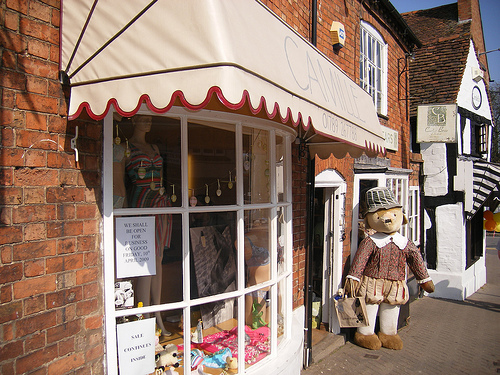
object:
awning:
[57, 0, 389, 159]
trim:
[66, 84, 389, 160]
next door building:
[408, 37, 499, 304]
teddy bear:
[331, 181, 437, 352]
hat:
[359, 182, 404, 218]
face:
[364, 206, 405, 236]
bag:
[331, 275, 371, 330]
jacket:
[341, 228, 432, 283]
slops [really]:
[347, 271, 413, 308]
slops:
[355, 273, 412, 309]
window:
[101, 98, 300, 373]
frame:
[102, 99, 290, 373]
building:
[398, 1, 497, 304]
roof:
[403, 33, 497, 125]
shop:
[404, 27, 500, 305]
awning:
[458, 157, 499, 221]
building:
[1, 0, 429, 374]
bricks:
[73, 232, 102, 253]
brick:
[44, 187, 87, 205]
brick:
[14, 310, 59, 339]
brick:
[23, 328, 47, 353]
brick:
[44, 315, 84, 349]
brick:
[53, 336, 75, 357]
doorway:
[310, 179, 342, 342]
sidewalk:
[300, 254, 499, 375]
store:
[58, 0, 390, 374]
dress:
[122, 136, 175, 254]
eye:
[392, 210, 399, 218]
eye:
[376, 215, 381, 221]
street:
[294, 228, 500, 373]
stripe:
[472, 163, 499, 176]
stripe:
[473, 171, 499, 187]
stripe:
[473, 168, 499, 183]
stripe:
[472, 200, 485, 208]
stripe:
[473, 180, 493, 196]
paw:
[418, 278, 436, 297]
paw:
[339, 277, 361, 298]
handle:
[340, 273, 357, 300]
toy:
[336, 287, 348, 300]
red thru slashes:
[348, 273, 414, 309]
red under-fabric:
[364, 277, 407, 306]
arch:
[313, 168, 346, 186]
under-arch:
[314, 166, 349, 188]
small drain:
[362, 350, 382, 363]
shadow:
[428, 279, 500, 315]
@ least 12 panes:
[111, 111, 288, 374]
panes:
[113, 306, 186, 374]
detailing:
[407, 102, 484, 274]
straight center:
[313, 123, 366, 151]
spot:
[338, 363, 348, 371]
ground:
[300, 231, 498, 374]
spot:
[342, 357, 350, 364]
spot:
[331, 361, 338, 370]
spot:
[316, 366, 323, 373]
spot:
[415, 366, 427, 373]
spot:
[324, 364, 331, 374]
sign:
[113, 315, 163, 374]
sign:
[114, 214, 159, 281]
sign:
[414, 103, 459, 147]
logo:
[338, 298, 366, 327]